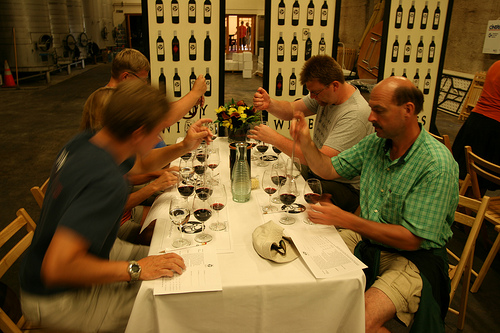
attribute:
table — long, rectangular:
[120, 130, 371, 333]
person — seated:
[289, 70, 464, 332]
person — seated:
[243, 50, 382, 216]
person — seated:
[100, 43, 208, 156]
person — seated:
[72, 83, 183, 249]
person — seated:
[17, 73, 192, 333]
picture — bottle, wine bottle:
[154, 26, 168, 64]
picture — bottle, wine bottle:
[171, 26, 183, 63]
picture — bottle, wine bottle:
[186, 28, 200, 63]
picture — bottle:
[203, 28, 214, 63]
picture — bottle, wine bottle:
[152, 0, 167, 26]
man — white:
[243, 50, 382, 216]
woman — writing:
[72, 83, 183, 249]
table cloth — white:
[239, 258, 372, 332]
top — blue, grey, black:
[20, 138, 119, 298]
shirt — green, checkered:
[330, 124, 458, 259]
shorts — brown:
[331, 220, 427, 328]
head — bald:
[370, 65, 432, 130]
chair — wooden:
[450, 180, 484, 330]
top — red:
[473, 52, 499, 128]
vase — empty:
[224, 135, 260, 206]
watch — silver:
[127, 255, 141, 285]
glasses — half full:
[260, 158, 308, 214]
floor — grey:
[17, 74, 81, 163]